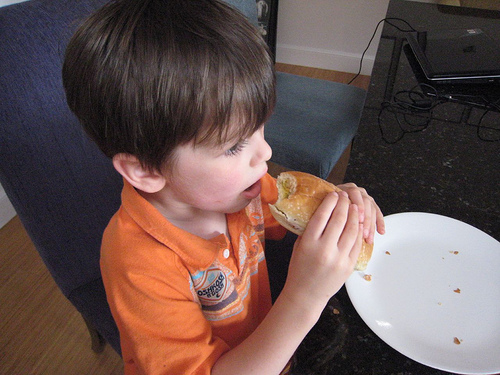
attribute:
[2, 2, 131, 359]
chair — purple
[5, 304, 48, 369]
floor — brown, hardwood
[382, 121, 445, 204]
countertop — granite, black